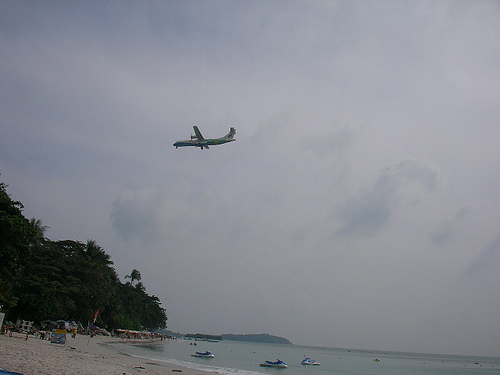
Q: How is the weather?
A: It is cloudy.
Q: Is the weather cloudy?
A: Yes, it is cloudy.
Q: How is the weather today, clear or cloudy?
A: It is cloudy.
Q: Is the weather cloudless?
A: No, it is cloudy.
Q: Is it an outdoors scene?
A: Yes, it is outdoors.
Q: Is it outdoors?
A: Yes, it is outdoors.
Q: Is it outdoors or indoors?
A: It is outdoors.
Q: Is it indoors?
A: No, it is outdoors.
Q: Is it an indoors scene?
A: No, it is outdoors.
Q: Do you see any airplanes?
A: Yes, there is an airplane.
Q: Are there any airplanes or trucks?
A: Yes, there is an airplane.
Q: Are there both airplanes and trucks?
A: No, there is an airplane but no trucks.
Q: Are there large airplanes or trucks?
A: Yes, there is a large airplane.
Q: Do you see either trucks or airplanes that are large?
A: Yes, the airplane is large.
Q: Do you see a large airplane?
A: Yes, there is a large airplane.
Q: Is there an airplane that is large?
A: Yes, there is an airplane that is large.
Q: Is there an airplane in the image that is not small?
A: Yes, there is a large airplane.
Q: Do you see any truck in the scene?
A: No, there are no trucks.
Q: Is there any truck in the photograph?
A: No, there are no trucks.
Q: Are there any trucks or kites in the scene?
A: No, there are no trucks or kites.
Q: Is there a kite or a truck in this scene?
A: No, there are no trucks or kites.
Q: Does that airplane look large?
A: Yes, the airplane is large.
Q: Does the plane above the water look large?
A: Yes, the airplane is large.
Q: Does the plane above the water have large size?
A: Yes, the airplane is large.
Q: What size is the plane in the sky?
A: The airplane is large.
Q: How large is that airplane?
A: The airplane is large.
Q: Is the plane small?
A: No, the plane is large.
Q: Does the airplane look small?
A: No, the airplane is large.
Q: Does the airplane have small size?
A: No, the airplane is large.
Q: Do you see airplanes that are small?
A: No, there is an airplane but it is large.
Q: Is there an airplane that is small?
A: No, there is an airplane but it is large.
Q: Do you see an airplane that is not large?
A: No, there is an airplane but it is large.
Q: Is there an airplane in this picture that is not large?
A: No, there is an airplane but it is large.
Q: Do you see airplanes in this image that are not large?
A: No, there is an airplane but it is large.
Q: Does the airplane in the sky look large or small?
A: The plane is large.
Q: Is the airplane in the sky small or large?
A: The plane is large.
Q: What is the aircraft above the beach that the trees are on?
A: The aircraft is an airplane.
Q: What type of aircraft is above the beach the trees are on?
A: The aircraft is an airplane.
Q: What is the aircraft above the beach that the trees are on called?
A: The aircraft is an airplane.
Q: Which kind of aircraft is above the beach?
A: The aircraft is an airplane.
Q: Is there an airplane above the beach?
A: Yes, there is an airplane above the beach.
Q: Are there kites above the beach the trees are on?
A: No, there is an airplane above the beach.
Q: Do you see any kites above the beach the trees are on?
A: No, there is an airplane above the beach.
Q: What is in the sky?
A: The airplane is in the sky.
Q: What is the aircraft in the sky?
A: The aircraft is an airplane.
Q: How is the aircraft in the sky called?
A: The aircraft is an airplane.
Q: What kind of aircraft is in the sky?
A: The aircraft is an airplane.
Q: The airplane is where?
A: The airplane is in the sky.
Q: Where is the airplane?
A: The airplane is in the sky.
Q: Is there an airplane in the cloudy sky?
A: Yes, there is an airplane in the sky.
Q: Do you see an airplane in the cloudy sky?
A: Yes, there is an airplane in the sky.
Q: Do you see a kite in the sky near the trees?
A: No, there is an airplane in the sky.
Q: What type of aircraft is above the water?
A: The aircraft is an airplane.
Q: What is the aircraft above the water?
A: The aircraft is an airplane.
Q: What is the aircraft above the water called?
A: The aircraft is an airplane.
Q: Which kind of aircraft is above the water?
A: The aircraft is an airplane.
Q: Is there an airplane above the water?
A: Yes, there is an airplane above the water.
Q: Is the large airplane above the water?
A: Yes, the plane is above the water.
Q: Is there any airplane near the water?
A: Yes, there is an airplane near the water.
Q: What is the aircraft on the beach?
A: The aircraft is an airplane.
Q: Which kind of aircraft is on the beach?
A: The aircraft is an airplane.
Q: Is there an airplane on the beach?
A: Yes, there is an airplane on the beach.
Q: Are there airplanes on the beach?
A: Yes, there is an airplane on the beach.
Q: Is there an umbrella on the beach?
A: No, there is an airplane on the beach.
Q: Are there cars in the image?
A: No, there are no cars.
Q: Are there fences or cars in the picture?
A: No, there are no cars or fences.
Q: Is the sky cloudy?
A: Yes, the sky is cloudy.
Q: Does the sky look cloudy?
A: Yes, the sky is cloudy.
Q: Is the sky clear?
A: No, the sky is cloudy.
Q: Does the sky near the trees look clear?
A: No, the sky is cloudy.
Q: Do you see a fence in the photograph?
A: No, there are no fences.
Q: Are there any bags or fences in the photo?
A: No, there are no fences or bags.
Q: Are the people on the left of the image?
A: Yes, the people are on the left of the image.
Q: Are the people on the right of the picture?
A: No, the people are on the left of the image.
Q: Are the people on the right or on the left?
A: The people are on the left of the image.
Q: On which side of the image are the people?
A: The people are on the left of the image.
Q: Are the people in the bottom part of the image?
A: Yes, the people are in the bottom of the image.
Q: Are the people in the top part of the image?
A: No, the people are in the bottom of the image.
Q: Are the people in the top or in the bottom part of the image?
A: The people are in the bottom of the image.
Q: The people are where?
A: The people are on the beach.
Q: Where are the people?
A: The people are on the beach.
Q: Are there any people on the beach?
A: Yes, there are people on the beach.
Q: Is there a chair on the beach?
A: No, there are people on the beach.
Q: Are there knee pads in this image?
A: No, there are no knee pads.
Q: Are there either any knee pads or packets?
A: No, there are no knee pads or packets.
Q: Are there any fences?
A: No, there are no fences.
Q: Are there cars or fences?
A: No, there are no fences or cars.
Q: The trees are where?
A: The trees are on the beach.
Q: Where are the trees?
A: The trees are on the beach.